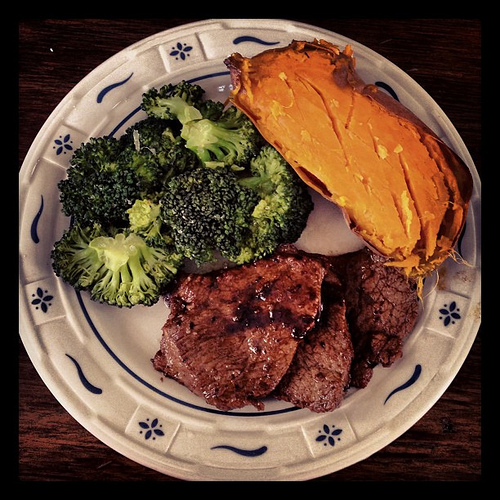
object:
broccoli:
[44, 203, 181, 312]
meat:
[150, 246, 331, 414]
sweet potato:
[220, 35, 478, 287]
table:
[18, 0, 484, 497]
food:
[140, 72, 214, 127]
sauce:
[320, 250, 377, 316]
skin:
[229, 98, 332, 205]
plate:
[13, 14, 484, 483]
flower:
[164, 34, 197, 63]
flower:
[309, 415, 346, 451]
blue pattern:
[60, 348, 107, 400]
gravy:
[226, 275, 317, 344]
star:
[27, 282, 57, 318]